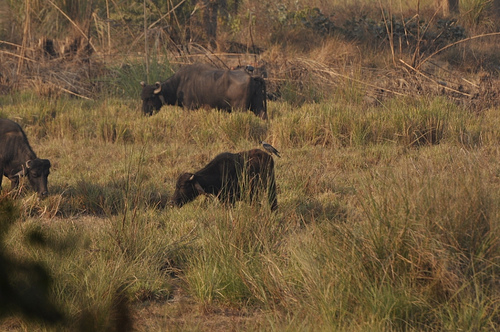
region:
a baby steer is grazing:
[160, 144, 309, 222]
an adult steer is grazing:
[0, 109, 55, 220]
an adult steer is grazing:
[129, 67, 286, 128]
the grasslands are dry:
[13, 103, 494, 330]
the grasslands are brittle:
[3, 100, 498, 307]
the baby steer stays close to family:
[155, 139, 309, 221]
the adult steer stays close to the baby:
[129, 65, 281, 122]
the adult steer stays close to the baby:
[5, 110, 55, 214]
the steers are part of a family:
[0, 66, 281, 218]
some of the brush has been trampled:
[5, 9, 470, 121]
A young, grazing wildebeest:
[169, 138, 279, 213]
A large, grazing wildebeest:
[0, 111, 54, 199]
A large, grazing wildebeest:
[134, 58, 268, 120]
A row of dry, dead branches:
[4, 3, 499, 104]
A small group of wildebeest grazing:
[0, 58, 286, 213]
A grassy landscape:
[6, 9, 493, 330]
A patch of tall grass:
[275, 128, 494, 330]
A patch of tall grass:
[182, 137, 281, 299]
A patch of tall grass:
[78, 145, 177, 293]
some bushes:
[291, 0, 461, 56]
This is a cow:
[165, 139, 307, 234]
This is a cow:
[129, 44, 289, 135]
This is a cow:
[0, 100, 62, 223]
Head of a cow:
[131, 70, 172, 130]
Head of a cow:
[158, 154, 203, 212]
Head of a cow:
[16, 145, 76, 205]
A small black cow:
[118, 130, 315, 218]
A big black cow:
[0, 98, 52, 198]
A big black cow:
[130, 66, 272, 113]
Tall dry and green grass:
[183, 200, 255, 317]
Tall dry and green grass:
[312, 208, 375, 299]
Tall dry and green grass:
[375, 213, 426, 328]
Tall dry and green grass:
[285, 70, 365, 150]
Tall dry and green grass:
[7, 195, 144, 325]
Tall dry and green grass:
[366, 88, 481, 146]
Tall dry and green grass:
[357, 127, 477, 271]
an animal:
[168, 155, 273, 218]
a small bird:
[259, 135, 282, 157]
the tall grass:
[314, 205, 451, 323]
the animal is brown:
[178, 155, 289, 217]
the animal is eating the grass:
[0, 112, 65, 202]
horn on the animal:
[149, 77, 162, 94]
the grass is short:
[330, 147, 387, 182]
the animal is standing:
[141, 64, 271, 116]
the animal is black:
[132, 69, 279, 122]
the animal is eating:
[2, 110, 56, 206]